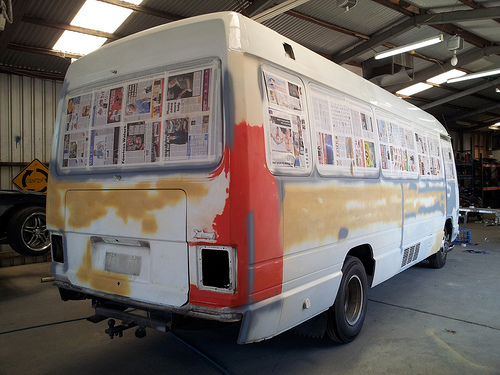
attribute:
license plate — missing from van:
[100, 249, 144, 276]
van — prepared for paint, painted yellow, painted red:
[42, 9, 460, 343]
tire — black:
[318, 253, 371, 345]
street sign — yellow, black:
[9, 156, 47, 195]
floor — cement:
[8, 219, 497, 375]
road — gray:
[6, 264, 498, 375]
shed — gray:
[3, 3, 498, 374]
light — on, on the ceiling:
[373, 32, 447, 60]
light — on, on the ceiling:
[446, 62, 499, 87]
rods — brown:
[279, 3, 498, 77]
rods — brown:
[6, 4, 192, 70]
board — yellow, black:
[12, 155, 48, 194]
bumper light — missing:
[41, 224, 70, 268]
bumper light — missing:
[196, 243, 237, 295]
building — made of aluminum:
[1, 0, 499, 230]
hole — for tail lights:
[47, 232, 66, 264]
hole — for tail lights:
[199, 246, 233, 288]